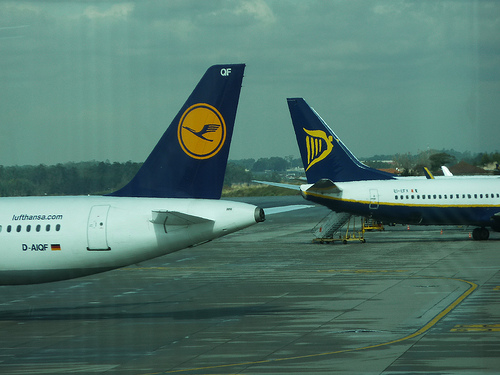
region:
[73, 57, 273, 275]
tail of a large airplane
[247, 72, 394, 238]
tail of a large airplane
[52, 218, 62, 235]
window on an airplane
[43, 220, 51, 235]
window on an airplane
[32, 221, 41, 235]
window on an airplane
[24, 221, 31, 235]
window on an airplane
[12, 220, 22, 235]
window on an airplane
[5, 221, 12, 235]
window on an airplane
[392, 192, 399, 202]
window on an airplane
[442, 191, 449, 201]
window on an airplane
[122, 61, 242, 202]
the blue and white tail of the plane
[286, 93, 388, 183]
the blue and white tail of the plane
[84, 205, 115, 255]
the door of the plane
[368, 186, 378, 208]
the door of the plane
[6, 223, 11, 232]
the window of the plane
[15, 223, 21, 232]
the window of the plane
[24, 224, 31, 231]
the window of the plane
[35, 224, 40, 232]
the window of the plane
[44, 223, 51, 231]
the window of the plane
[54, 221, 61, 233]
the window of the plane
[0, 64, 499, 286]
Two planes are together.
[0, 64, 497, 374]
The planes are on a runway.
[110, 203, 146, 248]
The plane is white.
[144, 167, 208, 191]
The plane is blue.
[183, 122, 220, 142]
A logo is on the plane.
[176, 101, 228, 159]
The logo is orange and blue.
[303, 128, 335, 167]
The logo is yellow.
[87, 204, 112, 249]
The plane has a rear door.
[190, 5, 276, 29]
Clouds are in the sky.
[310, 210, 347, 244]
Stairs are behind the plane.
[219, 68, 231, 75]
white lettering on the tail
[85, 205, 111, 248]
the passenger door is closed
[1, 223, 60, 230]
row of small windows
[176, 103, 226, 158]
the yellow logo is round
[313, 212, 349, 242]
a portable stair case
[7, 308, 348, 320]
a shadow on the runway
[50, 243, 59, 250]
a small flag on the plane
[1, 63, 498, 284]
two planes on the runway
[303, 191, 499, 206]
a yellow accent stripe on the plane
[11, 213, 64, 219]
black lettering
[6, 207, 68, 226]
web address of Lufthansa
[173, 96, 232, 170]
logo of the airline Lufthansa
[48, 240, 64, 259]
flag of the country Germany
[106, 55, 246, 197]
airplane has a blue tail fin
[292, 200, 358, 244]
stairs leading to the airplane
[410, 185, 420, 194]
flag of the country France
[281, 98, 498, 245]
blue white and yellow airplane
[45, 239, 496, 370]
yellow lines on the ground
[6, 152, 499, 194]
row of trees in the background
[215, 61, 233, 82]
the letters "QF" on the plane